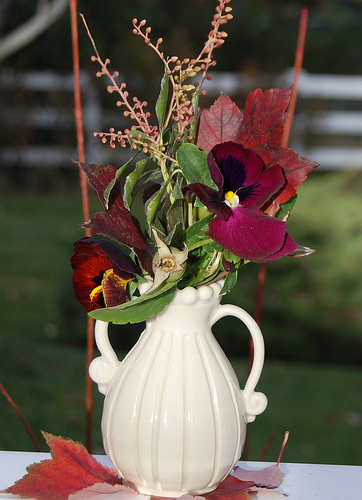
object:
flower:
[67, 201, 156, 314]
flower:
[76, 14, 167, 165]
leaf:
[171, 134, 219, 206]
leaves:
[0, 419, 290, 499]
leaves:
[72, 155, 120, 203]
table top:
[0, 448, 362, 499]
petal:
[16, 428, 130, 481]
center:
[222, 189, 239, 211]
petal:
[205, 206, 285, 259]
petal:
[180, 179, 233, 220]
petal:
[205, 139, 263, 202]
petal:
[238, 161, 287, 210]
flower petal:
[203, 206, 285, 262]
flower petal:
[182, 181, 231, 222]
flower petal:
[239, 162, 287, 206]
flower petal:
[206, 140, 264, 202]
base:
[124, 468, 230, 499]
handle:
[87, 298, 156, 399]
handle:
[211, 302, 270, 426]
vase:
[87, 273, 268, 497]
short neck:
[140, 300, 219, 332]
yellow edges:
[89, 265, 116, 302]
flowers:
[69, 160, 156, 314]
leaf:
[232, 82, 293, 147]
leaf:
[253, 144, 320, 217]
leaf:
[80, 213, 162, 278]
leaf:
[73, 156, 135, 210]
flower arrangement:
[70, 0, 322, 326]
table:
[0, 448, 362, 498]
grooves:
[143, 329, 175, 384]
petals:
[70, 235, 106, 299]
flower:
[179, 82, 323, 268]